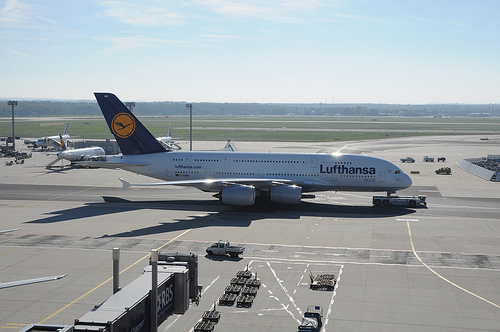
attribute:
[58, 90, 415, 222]
jet airplane — blue, white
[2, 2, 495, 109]
sky — cloudy, blue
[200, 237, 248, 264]
truck — white, pickup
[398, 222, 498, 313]
line — white, curved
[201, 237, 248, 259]
truck — white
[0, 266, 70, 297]
wing — white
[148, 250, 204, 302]
ramp — tall, grey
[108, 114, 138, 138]
circle — yellow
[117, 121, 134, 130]
bird — blue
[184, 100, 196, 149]
light — tall, silver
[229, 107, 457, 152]
runway — long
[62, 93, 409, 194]
plane — parked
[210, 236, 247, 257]
truck — white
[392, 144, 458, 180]
cars — parked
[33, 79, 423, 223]
airplane — large, white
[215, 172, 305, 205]
engines — turbines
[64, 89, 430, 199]
airplane — white, blue, gold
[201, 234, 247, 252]
truck — white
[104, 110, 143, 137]
circle — orange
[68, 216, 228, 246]
lines — orange, painted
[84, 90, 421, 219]
plane — huge, large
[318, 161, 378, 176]
word — blue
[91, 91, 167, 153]
tail — gold, blue